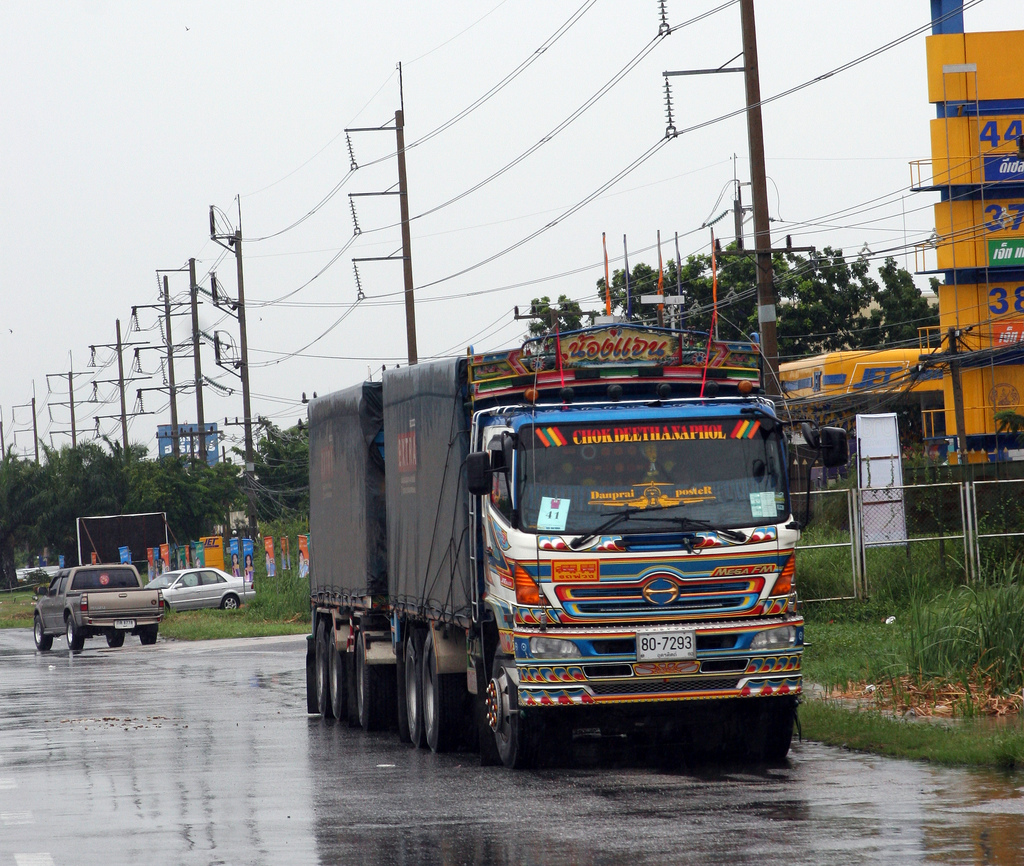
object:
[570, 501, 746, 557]
wiper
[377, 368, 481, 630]
tarp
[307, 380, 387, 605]
tarp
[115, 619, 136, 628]
plate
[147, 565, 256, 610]
car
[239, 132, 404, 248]
wire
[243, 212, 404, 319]
wire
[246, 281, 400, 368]
wire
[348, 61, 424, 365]
pole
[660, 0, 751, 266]
wires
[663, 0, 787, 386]
pole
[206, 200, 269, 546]
pole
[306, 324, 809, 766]
semi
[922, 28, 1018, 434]
sign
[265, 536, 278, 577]
flag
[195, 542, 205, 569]
flag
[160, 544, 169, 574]
flag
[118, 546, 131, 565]
flag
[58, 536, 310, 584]
line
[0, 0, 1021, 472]
sky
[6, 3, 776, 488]
poles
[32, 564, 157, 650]
truck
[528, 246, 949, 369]
leaves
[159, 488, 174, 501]
leaves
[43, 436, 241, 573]
tree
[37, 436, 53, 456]
leaves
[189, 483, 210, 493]
leaves